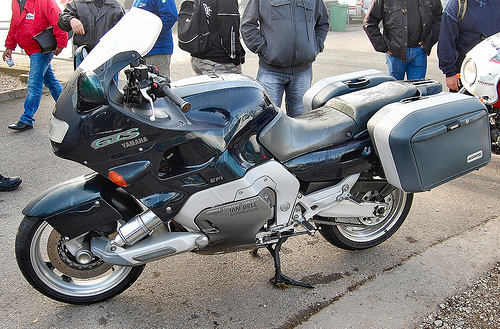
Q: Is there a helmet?
A: No, there are no helmets.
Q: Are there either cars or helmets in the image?
A: No, there are no helmets or cars.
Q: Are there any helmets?
A: No, there are no helmets.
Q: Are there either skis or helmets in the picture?
A: No, there are no helmets or skis.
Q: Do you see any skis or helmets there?
A: No, there are no helmets or skis.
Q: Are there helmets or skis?
A: No, there are no helmets or skis.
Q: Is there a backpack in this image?
A: Yes, there is a backpack.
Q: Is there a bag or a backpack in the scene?
A: Yes, there is a backpack.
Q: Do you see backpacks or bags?
A: Yes, there is a backpack.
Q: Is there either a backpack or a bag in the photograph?
A: Yes, there is a backpack.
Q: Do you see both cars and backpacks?
A: No, there is a backpack but no cars.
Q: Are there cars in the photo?
A: No, there are no cars.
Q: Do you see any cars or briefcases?
A: No, there are no cars or briefcases.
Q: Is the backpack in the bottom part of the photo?
A: No, the backpack is in the top of the image.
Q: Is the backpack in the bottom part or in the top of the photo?
A: The backpack is in the top of the image.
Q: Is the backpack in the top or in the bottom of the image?
A: The backpack is in the top of the image.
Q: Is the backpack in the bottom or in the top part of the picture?
A: The backpack is in the top of the image.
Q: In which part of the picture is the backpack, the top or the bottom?
A: The backpack is in the top of the image.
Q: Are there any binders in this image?
A: No, there are no binders.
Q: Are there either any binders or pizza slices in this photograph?
A: No, there are no binders or pizza slices.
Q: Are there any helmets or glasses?
A: No, there are no helmets or glasses.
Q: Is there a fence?
A: No, there are no fences.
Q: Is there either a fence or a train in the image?
A: No, there are no fences or trains.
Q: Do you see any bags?
A: Yes, there is a bag.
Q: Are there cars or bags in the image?
A: Yes, there is a bag.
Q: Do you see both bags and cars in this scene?
A: No, there is a bag but no cars.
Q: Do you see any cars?
A: No, there are no cars.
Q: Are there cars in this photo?
A: No, there are no cars.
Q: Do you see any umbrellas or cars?
A: No, there are no cars or umbrellas.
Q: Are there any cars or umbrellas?
A: No, there are no cars or umbrellas.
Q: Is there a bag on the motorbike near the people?
A: Yes, there is a bag on the motorcycle.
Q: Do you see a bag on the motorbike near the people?
A: Yes, there is a bag on the motorcycle.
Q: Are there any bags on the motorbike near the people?
A: Yes, there is a bag on the motorcycle.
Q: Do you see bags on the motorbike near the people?
A: Yes, there is a bag on the motorcycle.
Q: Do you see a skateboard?
A: No, there are no skateboards.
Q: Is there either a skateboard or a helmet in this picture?
A: No, there are no skateboards or helmets.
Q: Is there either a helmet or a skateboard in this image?
A: No, there are no skateboards or helmets.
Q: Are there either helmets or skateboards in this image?
A: No, there are no skateboards or helmets.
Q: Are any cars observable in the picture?
A: No, there are no cars.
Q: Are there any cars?
A: No, there are no cars.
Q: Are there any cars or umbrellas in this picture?
A: No, there are no cars or umbrellas.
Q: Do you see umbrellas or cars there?
A: No, there are no cars or umbrellas.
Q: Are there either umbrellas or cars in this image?
A: No, there are no cars or umbrellas.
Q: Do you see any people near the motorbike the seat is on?
A: Yes, there are people near the motorbike.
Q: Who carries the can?
A: The people carry the can.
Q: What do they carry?
A: The people carry a can.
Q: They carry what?
A: The people carry a can.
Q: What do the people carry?
A: The people carry a can.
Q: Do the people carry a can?
A: Yes, the people carry a can.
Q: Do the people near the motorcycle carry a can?
A: Yes, the people carry a can.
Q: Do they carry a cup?
A: No, the people carry a can.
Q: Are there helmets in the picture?
A: No, there are no helmets.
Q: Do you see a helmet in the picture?
A: No, there are no helmets.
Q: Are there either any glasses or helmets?
A: No, there are no helmets or glasses.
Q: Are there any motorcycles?
A: Yes, there is a motorcycle.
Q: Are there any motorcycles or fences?
A: Yes, there is a motorcycle.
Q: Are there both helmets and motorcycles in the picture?
A: No, there is a motorcycle but no helmets.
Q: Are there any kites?
A: No, there are no kites.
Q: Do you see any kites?
A: No, there are no kites.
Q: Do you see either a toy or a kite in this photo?
A: No, there are no kites or toys.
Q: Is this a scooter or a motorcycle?
A: This is a motorcycle.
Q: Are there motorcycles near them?
A: Yes, there is a motorcycle near the people.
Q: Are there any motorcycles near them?
A: Yes, there is a motorcycle near the people.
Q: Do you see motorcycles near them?
A: Yes, there is a motorcycle near the people.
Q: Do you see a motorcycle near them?
A: Yes, there is a motorcycle near the people.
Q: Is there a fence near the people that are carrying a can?
A: No, there is a motorcycle near the people.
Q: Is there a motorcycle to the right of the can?
A: Yes, there is a motorcycle to the right of the can.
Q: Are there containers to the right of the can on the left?
A: No, there is a motorcycle to the right of the can.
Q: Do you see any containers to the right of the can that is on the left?
A: No, there is a motorcycle to the right of the can.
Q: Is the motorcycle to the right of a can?
A: Yes, the motorcycle is to the right of a can.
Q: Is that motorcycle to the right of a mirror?
A: No, the motorcycle is to the right of a can.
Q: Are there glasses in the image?
A: No, there are no glasses.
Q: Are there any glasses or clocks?
A: No, there are no glasses or clocks.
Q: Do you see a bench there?
A: No, there are no benches.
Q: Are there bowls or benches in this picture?
A: No, there are no benches or bowls.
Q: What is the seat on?
A: The seat is on the motorcycle.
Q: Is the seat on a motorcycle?
A: Yes, the seat is on a motorcycle.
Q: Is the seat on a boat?
A: No, the seat is on a motorcycle.